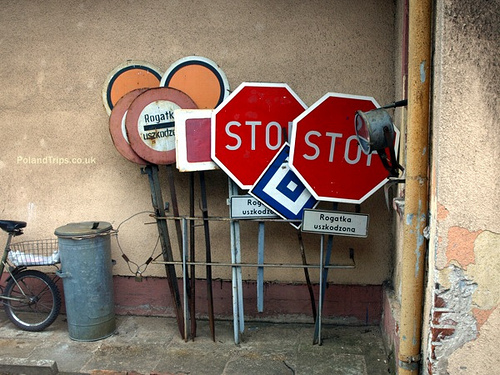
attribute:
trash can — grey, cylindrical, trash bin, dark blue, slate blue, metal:
[52, 215, 122, 345]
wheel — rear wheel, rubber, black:
[3, 268, 63, 333]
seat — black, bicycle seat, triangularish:
[0, 217, 31, 240]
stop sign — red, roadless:
[284, 89, 404, 208]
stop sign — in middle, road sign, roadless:
[207, 80, 312, 315]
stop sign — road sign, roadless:
[285, 87, 402, 352]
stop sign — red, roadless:
[209, 76, 316, 193]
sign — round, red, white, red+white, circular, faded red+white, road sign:
[123, 86, 201, 173]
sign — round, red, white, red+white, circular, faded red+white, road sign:
[108, 87, 173, 168]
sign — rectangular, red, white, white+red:
[178, 110, 214, 175]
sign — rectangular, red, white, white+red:
[172, 107, 222, 172]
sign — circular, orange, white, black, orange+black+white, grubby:
[159, 54, 233, 120]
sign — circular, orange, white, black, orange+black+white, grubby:
[98, 58, 163, 127]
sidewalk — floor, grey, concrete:
[0, 307, 392, 375]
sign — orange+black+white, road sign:
[159, 56, 234, 345]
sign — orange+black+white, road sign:
[100, 57, 191, 348]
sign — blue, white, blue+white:
[246, 140, 322, 233]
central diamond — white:
[285, 179, 298, 193]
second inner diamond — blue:
[274, 168, 310, 201]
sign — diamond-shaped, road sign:
[244, 122, 326, 348]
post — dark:
[196, 172, 222, 343]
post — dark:
[142, 162, 191, 342]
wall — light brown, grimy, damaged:
[0, 1, 395, 297]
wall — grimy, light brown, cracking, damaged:
[421, 1, 498, 375]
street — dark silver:
[0, 304, 398, 374]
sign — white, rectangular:
[301, 208, 370, 240]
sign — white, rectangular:
[228, 195, 285, 219]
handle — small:
[53, 266, 72, 280]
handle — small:
[111, 256, 118, 267]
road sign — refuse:
[248, 140, 326, 351]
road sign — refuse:
[122, 85, 202, 342]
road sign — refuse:
[157, 52, 231, 350]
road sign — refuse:
[206, 80, 315, 322]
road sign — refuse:
[106, 85, 200, 345]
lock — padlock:
[133, 269, 145, 284]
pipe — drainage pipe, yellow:
[395, 1, 434, 375]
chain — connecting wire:
[114, 207, 167, 276]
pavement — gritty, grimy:
[0, 307, 390, 375]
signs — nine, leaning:
[99, 54, 404, 349]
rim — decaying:
[159, 54, 231, 112]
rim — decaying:
[98, 57, 167, 119]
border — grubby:
[100, 58, 163, 117]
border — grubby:
[159, 54, 234, 116]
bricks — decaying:
[0, 270, 405, 375]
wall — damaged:
[379, 1, 410, 367]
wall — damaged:
[0, 266, 384, 328]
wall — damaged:
[380, 280, 403, 375]